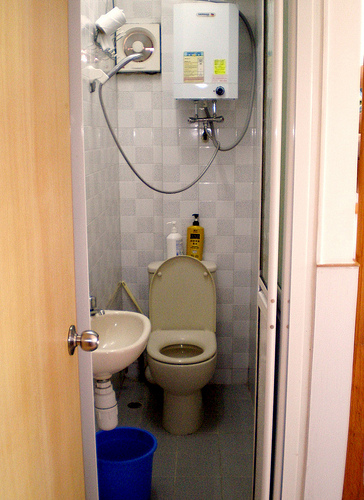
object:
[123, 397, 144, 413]
drain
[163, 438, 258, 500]
floor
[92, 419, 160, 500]
bucket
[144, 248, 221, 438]
toilet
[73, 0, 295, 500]
bathroom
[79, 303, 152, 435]
sink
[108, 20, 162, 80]
fan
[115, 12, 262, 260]
wall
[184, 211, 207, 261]
bottle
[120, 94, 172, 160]
tile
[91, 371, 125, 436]
pipe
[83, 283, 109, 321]
faucet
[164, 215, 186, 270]
bottle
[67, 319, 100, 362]
knob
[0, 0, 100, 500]
door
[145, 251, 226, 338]
lid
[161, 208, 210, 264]
products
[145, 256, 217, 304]
tank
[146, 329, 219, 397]
bowl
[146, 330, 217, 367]
seat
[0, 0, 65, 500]
wood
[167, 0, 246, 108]
box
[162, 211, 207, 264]
bottles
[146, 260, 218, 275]
back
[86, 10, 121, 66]
shower